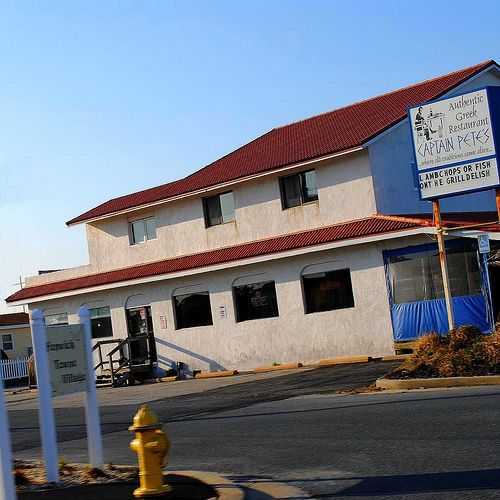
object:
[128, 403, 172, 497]
fire hydrant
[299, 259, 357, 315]
window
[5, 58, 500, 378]
building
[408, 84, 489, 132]
sign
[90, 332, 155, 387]
staircase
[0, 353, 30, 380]
fence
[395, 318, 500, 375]
grass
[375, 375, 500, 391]
curb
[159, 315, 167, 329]
handicapped sign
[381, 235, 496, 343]
tarp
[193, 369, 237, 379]
marker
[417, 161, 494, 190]
letters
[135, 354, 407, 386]
blocks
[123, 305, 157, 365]
door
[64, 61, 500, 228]
roof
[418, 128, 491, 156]
captain pete's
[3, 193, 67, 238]
clouds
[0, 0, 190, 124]
blue sky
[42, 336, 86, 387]
sign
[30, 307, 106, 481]
posts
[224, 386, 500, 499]
road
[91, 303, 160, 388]
entrance